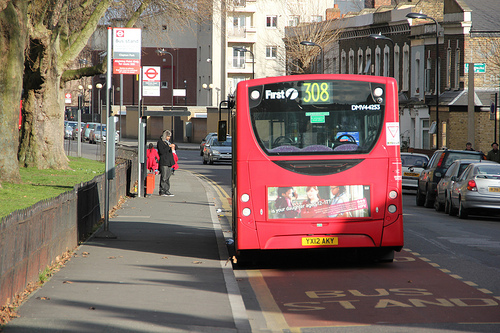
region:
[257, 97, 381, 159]
the bus has a windshield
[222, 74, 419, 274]
the bus is big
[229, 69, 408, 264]
the bus is red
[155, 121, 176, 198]
the man is standing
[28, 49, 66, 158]
the tree is big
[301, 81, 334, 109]
the numbers are yellow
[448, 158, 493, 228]
the car is parked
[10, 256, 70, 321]
the leaves are on the sidewalk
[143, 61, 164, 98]
the sign is red and white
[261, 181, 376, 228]
the banner is on the bus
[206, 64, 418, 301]
a red public bus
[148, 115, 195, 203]
a person standing on the side walk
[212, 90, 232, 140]
rear view mirror on a bus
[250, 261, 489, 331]
red and yellow painting on road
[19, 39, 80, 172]
a large tree trunk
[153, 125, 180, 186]
a person wearing a coat with fake fur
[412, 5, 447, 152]
a tall black street light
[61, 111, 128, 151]
several cars parked on side of road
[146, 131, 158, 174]
a woman wearing a red jacket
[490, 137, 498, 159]
a man wearing a hat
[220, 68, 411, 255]
Red bus on a road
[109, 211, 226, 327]
Gray sidewalk by a road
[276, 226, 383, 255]
Yellow sign on a red bus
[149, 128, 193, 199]
Person standing on a sidewalk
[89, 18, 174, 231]
Bus stop on a sidewalk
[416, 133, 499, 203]
Cars parked on a road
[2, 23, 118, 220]
Tree in grass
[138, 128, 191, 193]
People on a sidewalk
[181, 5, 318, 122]
Gray building by a road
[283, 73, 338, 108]
Sign on a bus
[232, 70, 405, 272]
The back of a large red bus.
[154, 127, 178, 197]
A young man standing in the sidewalk.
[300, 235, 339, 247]
The registration plate of the bus.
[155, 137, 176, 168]
The man is wearing a black jacket.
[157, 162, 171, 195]
The guy is wearing a pair of black jeans.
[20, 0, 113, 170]
A large tree near the the sidewalk.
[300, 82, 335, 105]
The route number this bus is taking.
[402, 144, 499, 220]
A bunch of cars stuck in traffic.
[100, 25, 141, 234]
A message on top of a pole.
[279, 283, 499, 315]
A sign on the road saying bus stand.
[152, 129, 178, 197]
man in black coat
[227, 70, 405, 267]
back of red bus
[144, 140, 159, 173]
woman in yellow coat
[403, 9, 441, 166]
tall black street lamp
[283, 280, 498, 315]
sign saying bus stand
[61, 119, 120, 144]
line of cars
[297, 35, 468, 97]
row of building windows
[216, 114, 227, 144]
rear view mirror on bus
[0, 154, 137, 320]
brick wall separating grass from sidewalk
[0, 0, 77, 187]
two trees overlooking street